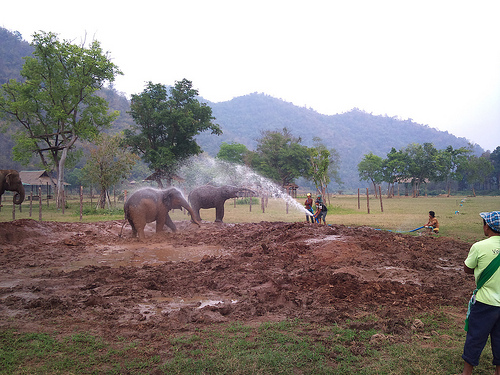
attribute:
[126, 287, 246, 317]
mud puddle — small , mud 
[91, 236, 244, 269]
pool — watery, mud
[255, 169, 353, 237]
dudes — spraying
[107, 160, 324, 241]
elephant — happy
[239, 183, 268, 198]
trunk — elephants, raised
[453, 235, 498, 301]
shirt — man's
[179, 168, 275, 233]
elephant — brown , large 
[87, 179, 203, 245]
elephant — joins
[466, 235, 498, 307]
shirt — man's 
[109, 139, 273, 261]
elephants — mud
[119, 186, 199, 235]
elephant — one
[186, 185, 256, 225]
elephant — one, on right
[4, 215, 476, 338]
dirt — red, brown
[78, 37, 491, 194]
mountains — distant, hazy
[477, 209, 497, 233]
hat — blue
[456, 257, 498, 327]
bag — green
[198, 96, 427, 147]
mountains — tree covered 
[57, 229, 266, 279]
lake — little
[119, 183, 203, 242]
elephant — large , brown 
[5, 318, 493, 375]
grass — sparse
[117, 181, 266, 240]
elephants — adult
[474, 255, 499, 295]
strap — green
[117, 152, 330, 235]
bath — festival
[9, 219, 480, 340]
muck — wet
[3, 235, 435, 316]
pit — giant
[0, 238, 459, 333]
mud — water filled pool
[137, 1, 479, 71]
sky — bright , empty 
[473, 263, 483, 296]
stripe — blue 